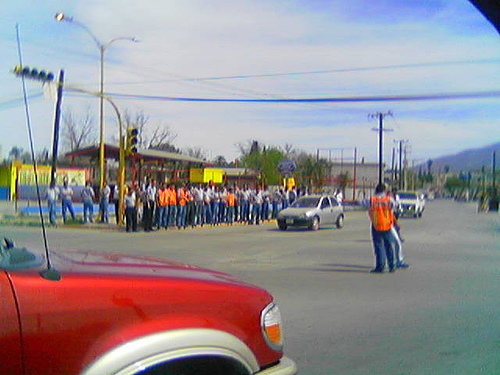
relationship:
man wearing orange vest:
[370, 178, 398, 282] [367, 193, 395, 232]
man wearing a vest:
[370, 178, 398, 282] [367, 193, 395, 232]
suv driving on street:
[2, 233, 300, 375] [1, 194, 495, 375]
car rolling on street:
[276, 190, 346, 230] [1, 194, 495, 375]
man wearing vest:
[370, 178, 398, 282] [367, 193, 395, 232]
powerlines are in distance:
[283, 113, 423, 195] [217, 107, 496, 211]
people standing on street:
[117, 182, 300, 234] [1, 194, 495, 375]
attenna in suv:
[14, 21, 60, 279] [2, 233, 300, 375]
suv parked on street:
[2, 233, 300, 375] [1, 194, 495, 375]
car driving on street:
[276, 190, 346, 230] [1, 194, 495, 375]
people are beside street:
[117, 182, 300, 234] [1, 194, 495, 375]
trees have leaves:
[226, 145, 500, 197] [220, 140, 499, 193]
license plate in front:
[280, 215, 299, 225] [279, 205, 315, 232]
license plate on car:
[280, 215, 299, 225] [276, 190, 346, 230]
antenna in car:
[14, 21, 60, 279] [2, 233, 300, 375]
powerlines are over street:
[283, 113, 423, 195] [1, 194, 495, 375]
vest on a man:
[367, 193, 395, 232] [370, 178, 398, 282]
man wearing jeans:
[370, 178, 398, 282] [373, 226, 396, 277]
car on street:
[276, 190, 346, 230] [1, 194, 495, 375]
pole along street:
[377, 108, 387, 197] [1, 194, 495, 375]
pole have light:
[51, 10, 142, 229] [51, 12, 150, 50]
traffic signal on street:
[14, 67, 138, 229] [1, 194, 495, 375]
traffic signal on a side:
[14, 67, 138, 229] [18, 193, 253, 237]